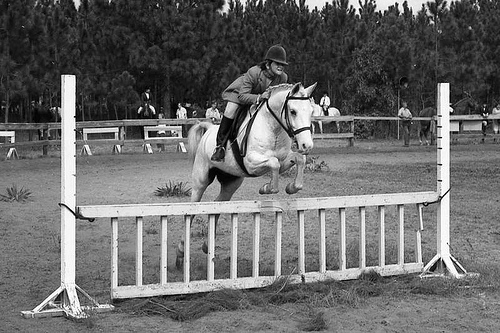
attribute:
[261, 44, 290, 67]
helmet — dark, black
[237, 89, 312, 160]
reins — black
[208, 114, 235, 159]
boots — black, dark, high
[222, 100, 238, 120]
pants — light colored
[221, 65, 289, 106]
coat — gray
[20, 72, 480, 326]
fence — large, white, wood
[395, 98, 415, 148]
man — watching, distant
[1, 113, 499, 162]
fence — wood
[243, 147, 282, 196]
leg — bent, curled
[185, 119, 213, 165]
tail — white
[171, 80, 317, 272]
horse — white, jumping